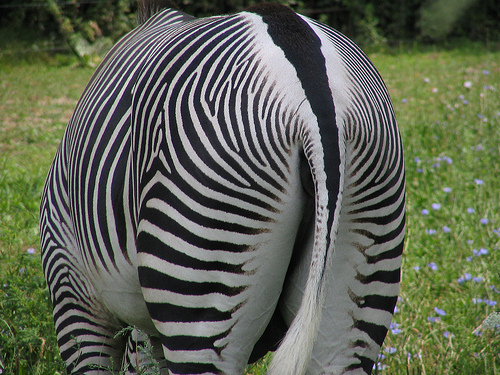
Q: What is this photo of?
A: A zebra.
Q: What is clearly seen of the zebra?
A: The zebra butt.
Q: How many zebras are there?
A: One.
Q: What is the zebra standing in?
A: Grass.